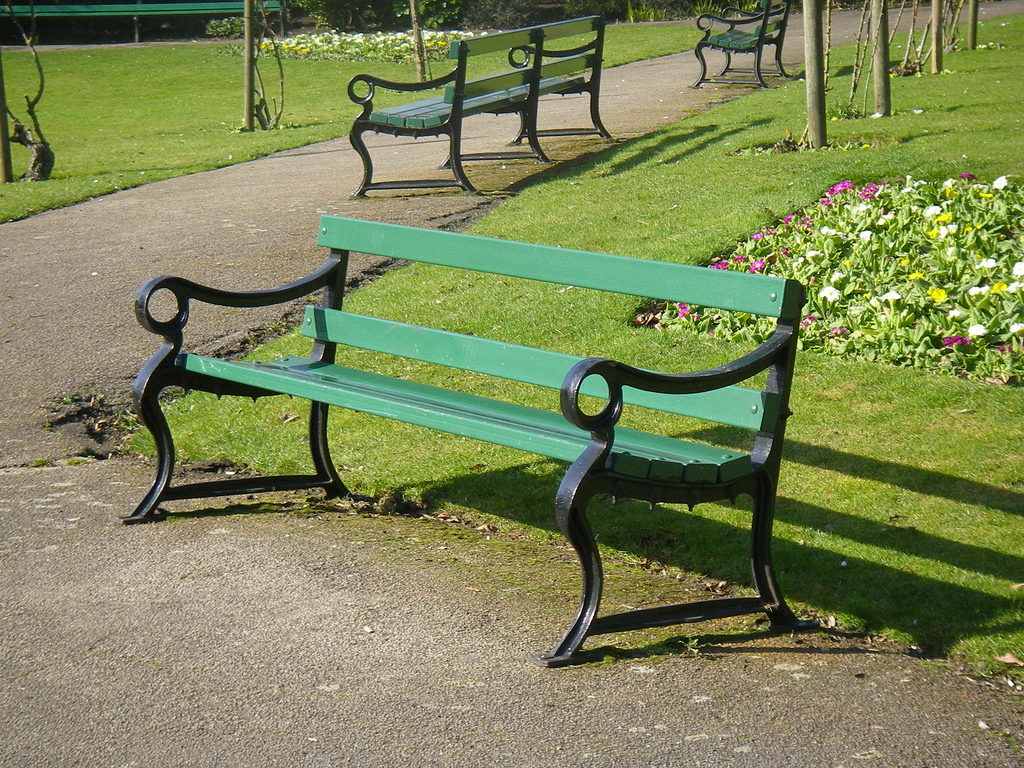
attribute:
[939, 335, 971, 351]
flowers — behind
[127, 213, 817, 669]
park bench — green, black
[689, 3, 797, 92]
bench — black, green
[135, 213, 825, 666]
bench — black, green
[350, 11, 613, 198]
bench — black, green